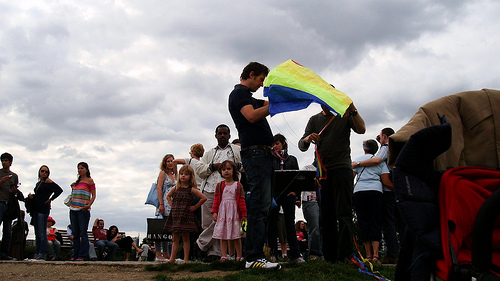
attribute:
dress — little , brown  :
[164, 185, 198, 235]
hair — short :
[240, 60, 269, 79]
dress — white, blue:
[158, 170, 180, 211]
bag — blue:
[148, 176, 165, 204]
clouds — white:
[3, 4, 494, 205]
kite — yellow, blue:
[260, 50, 353, 136]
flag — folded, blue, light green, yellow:
[260, 49, 375, 156]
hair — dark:
[236, 60, 271, 83]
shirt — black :
[223, 85, 280, 145]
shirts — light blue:
[353, 143, 393, 193]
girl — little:
[161, 166, 208, 268]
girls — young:
[169, 163, 242, 263]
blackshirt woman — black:
[29, 163, 62, 260]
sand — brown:
[51, 266, 88, 279]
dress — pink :
[213, 180, 244, 239]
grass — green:
[309, 257, 339, 271]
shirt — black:
[242, 91, 292, 138]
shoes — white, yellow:
[223, 248, 288, 273]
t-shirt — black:
[32, 181, 53, 200]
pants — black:
[30, 213, 52, 251]